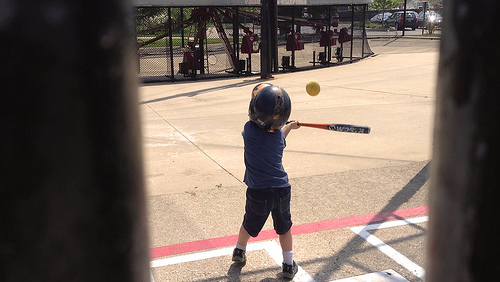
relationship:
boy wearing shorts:
[232, 83, 300, 278] [243, 187, 298, 234]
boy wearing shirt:
[232, 83, 300, 278] [242, 118, 292, 188]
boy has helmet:
[232, 83, 300, 278] [248, 81, 292, 126]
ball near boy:
[305, 81, 320, 97] [232, 83, 300, 278]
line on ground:
[143, 202, 428, 259] [148, 31, 435, 279]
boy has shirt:
[228, 76, 308, 271] [244, 118, 291, 185]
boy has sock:
[232, 83, 300, 278] [283, 250, 295, 266]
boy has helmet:
[232, 83, 300, 278] [244, 81, 292, 128]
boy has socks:
[232, 83, 300, 278] [282, 246, 307, 276]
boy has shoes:
[232, 83, 300, 278] [262, 256, 319, 275]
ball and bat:
[301, 72, 324, 99] [285, 103, 380, 146]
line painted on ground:
[148, 202, 429, 267] [148, 31, 435, 279]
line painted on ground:
[352, 224, 422, 275] [148, 31, 435, 279]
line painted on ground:
[261, 237, 311, 280] [148, 31, 435, 279]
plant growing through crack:
[185, 182, 199, 197] [146, 182, 244, 197]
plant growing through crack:
[215, 182, 225, 187] [146, 182, 244, 197]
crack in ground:
[146, 182, 244, 197] [137, 21, 443, 280]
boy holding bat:
[232, 83, 300, 278] [289, 104, 404, 166]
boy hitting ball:
[232, 83, 300, 278] [305, 79, 320, 96]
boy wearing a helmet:
[232, 83, 300, 278] [244, 79, 294, 134]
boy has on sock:
[232, 83, 300, 278] [281, 249, 293, 264]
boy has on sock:
[232, 83, 300, 278] [230, 237, 247, 252]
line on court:
[148, 202, 429, 267] [139, 45, 431, 281]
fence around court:
[204, 20, 341, 65] [139, 45, 431, 281]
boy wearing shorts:
[232, 83, 300, 278] [239, 176, 292, 238]